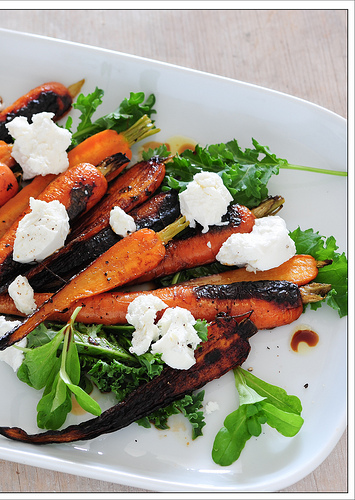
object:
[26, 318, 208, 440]
kale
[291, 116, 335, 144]
wall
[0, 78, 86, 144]
carrot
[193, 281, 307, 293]
burn mark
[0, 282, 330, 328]
carrot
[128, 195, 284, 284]
carrot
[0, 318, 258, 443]
carrot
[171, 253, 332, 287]
carrot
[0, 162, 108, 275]
carrot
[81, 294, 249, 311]
seasoning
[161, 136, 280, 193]
pizza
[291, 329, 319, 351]
dressing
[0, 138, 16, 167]
carrot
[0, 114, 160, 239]
carrot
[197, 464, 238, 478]
reflection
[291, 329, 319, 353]
oil drop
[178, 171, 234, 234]
cheese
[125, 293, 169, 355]
cheese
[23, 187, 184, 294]
carrot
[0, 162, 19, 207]
carrot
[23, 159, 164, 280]
carrot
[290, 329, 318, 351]
juice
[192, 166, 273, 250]
chees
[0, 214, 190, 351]
carrot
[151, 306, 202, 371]
cheese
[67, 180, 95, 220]
burn mark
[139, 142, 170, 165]
leaves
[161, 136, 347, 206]
greens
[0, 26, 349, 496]
dish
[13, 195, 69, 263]
cheese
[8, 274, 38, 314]
cheese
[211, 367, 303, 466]
herb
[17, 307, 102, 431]
herb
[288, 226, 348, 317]
herb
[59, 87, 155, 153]
herb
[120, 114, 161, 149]
stem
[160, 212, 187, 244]
stem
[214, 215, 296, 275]
cheese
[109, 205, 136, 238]
cheese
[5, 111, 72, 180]
cheese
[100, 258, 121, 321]
grains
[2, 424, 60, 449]
tip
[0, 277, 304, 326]
skin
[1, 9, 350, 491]
table